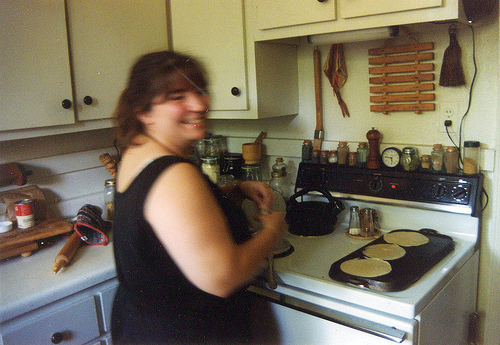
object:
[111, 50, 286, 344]
woman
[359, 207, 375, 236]
shaker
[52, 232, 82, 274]
pin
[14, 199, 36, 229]
can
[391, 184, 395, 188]
light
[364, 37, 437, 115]
grate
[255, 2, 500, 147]
wall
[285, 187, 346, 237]
kettle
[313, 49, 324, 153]
brush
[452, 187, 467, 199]
knob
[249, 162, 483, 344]
stove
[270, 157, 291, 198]
jar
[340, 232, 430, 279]
cakes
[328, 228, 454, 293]
griddle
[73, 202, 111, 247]
mitt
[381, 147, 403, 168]
timer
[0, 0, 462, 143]
cupboards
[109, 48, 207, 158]
hair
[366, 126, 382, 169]
grinder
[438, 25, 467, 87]
broom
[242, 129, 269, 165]
pestle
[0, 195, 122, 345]
counter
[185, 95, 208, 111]
nose